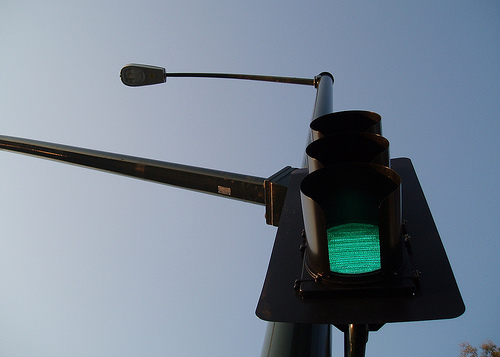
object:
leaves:
[455, 337, 498, 354]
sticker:
[216, 185, 233, 196]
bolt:
[293, 275, 314, 300]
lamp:
[118, 61, 165, 87]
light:
[256, 107, 467, 355]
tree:
[465, 335, 495, 354]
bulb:
[120, 62, 167, 87]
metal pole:
[303, 70, 333, 175]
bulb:
[325, 217, 382, 276]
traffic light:
[300, 105, 416, 312]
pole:
[339, 319, 365, 356]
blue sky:
[0, 0, 500, 357]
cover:
[301, 165, 401, 204]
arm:
[0, 133, 267, 204]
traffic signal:
[261, 108, 464, 357]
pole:
[247, 71, 336, 357]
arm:
[167, 69, 312, 85]